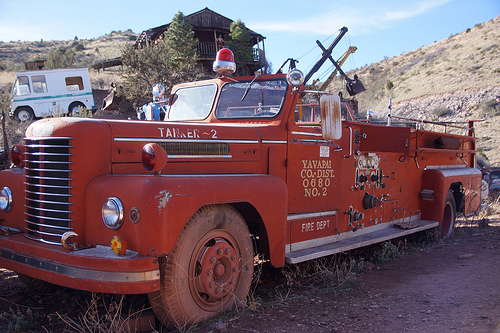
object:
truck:
[0, 49, 484, 333]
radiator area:
[17, 135, 81, 249]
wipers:
[237, 72, 264, 102]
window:
[213, 79, 288, 120]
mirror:
[318, 96, 342, 141]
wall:
[216, 82, 363, 141]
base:
[212, 48, 234, 75]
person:
[205, 25, 235, 52]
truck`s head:
[0, 115, 171, 288]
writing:
[299, 160, 332, 196]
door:
[285, 103, 342, 214]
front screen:
[168, 80, 285, 119]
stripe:
[7, 69, 98, 121]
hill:
[0, 17, 500, 222]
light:
[0, 185, 12, 210]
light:
[101, 196, 123, 228]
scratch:
[154, 190, 173, 214]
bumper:
[0, 229, 162, 294]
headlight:
[102, 197, 124, 231]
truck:
[49, 58, 494, 324]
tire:
[149, 206, 262, 323]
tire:
[439, 188, 460, 241]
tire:
[70, 103, 88, 119]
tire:
[15, 108, 32, 124]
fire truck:
[0, 47, 484, 329]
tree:
[117, 13, 257, 117]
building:
[24, 7, 265, 77]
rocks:
[379, 89, 500, 197]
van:
[4, 66, 95, 125]